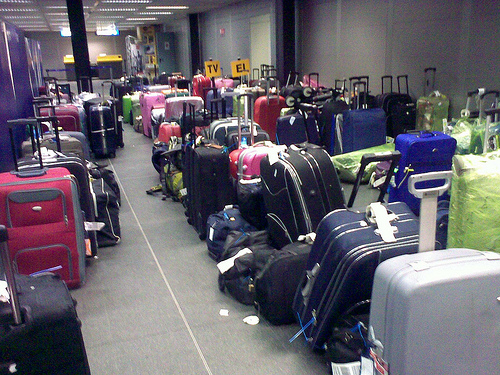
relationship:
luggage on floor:
[0, 117, 86, 289] [65, 117, 392, 372]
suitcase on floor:
[250, 73, 284, 140] [65, 117, 392, 372]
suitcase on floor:
[366, 247, 494, 371] [65, 117, 392, 372]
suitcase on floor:
[2, 224, 92, 374] [65, 117, 392, 372]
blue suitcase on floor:
[291, 201, 441, 353] [65, 117, 392, 372]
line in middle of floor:
[103, 151, 218, 373] [74, 112, 337, 372]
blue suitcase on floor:
[387, 131, 457, 219] [58, 121, 394, 375]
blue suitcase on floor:
[333, 81, 385, 159] [58, 121, 394, 375]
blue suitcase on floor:
[293, 199, 428, 351] [58, 121, 394, 375]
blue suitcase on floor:
[185, 144, 229, 243] [58, 121, 394, 375]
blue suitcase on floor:
[271, 111, 318, 142] [58, 121, 394, 375]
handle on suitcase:
[245, 147, 317, 179] [275, 130, 366, 224]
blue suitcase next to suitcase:
[291, 201, 441, 353] [363, 169, 497, 373]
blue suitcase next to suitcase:
[388, 131, 457, 219] [382, 70, 416, 137]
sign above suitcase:
[228, 59, 252, 76] [233, 85, 261, 117]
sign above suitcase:
[228, 59, 252, 76] [247, 75, 286, 141]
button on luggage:
[31, 204, 42, 211] [0, 117, 86, 289]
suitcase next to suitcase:
[259, 144, 351, 249] [282, 185, 398, 344]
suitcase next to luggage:
[0, 224, 92, 375] [0, 117, 86, 289]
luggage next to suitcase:
[0, 117, 86, 289] [20, 157, 100, 267]